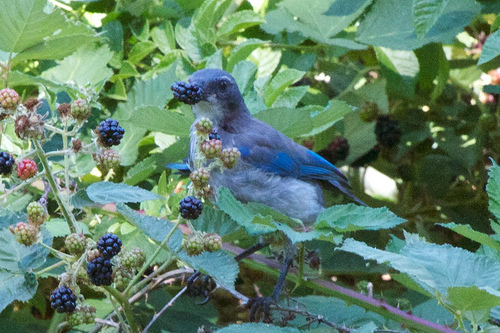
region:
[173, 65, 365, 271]
A bird in the photo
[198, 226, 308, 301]
Bird's legs in the photo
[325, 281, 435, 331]
A twig in the photo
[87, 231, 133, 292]
Blue fruits in the photo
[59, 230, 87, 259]
Green fruits in the photo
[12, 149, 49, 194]
Red fruits in the photo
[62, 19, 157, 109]
Leaves in the photo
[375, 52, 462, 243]
Trees in the photo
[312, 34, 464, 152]
Leaves in the photo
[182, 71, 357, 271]
Bird in the photo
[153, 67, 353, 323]
a bird eating berries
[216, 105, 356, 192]
a blue and grey wing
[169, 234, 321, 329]
the claws are attached to a twig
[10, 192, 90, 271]
berries that are green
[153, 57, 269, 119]
a berry in a bird's mouth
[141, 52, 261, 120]
a bird with a berry in it's mouth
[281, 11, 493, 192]
berries surrounded by green leaves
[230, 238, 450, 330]
thorns on a branch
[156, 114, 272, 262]
one blackberry on a stem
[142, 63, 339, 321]
one bird on a twig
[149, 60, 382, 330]
a bluebird eating blackberries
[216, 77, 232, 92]
black eye on a bluebird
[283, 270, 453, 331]
thorny stem of a blackberry plant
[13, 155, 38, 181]
an unripe red blackberry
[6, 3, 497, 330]
green leaves of a blackberry bush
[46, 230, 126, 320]
three ripe blackberries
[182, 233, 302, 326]
a pair of black birds legs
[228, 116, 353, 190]
blue wing of a bird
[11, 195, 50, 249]
green unripe blackberries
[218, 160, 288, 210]
feathery chest of a bird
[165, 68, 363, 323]
blue bird in the leaves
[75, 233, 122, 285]
black berries on the leaves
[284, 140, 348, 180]
blue wing on the bird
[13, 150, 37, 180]
red raspberry in the leaves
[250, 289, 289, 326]
foot of the bird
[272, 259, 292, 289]
leg of the bird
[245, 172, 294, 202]
feathers on the bird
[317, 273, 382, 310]
tree branch in the leaves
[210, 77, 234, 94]
eye of the bird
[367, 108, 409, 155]
black berry on a branch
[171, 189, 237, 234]
Blue fruits in the photo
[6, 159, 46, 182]
Red fruits in the photo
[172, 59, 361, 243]
A bird on the tree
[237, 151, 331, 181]
Blue feathers in the photo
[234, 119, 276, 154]
Gray feathers in the photo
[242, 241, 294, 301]
Legs in the photo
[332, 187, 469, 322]
Trees in the photo